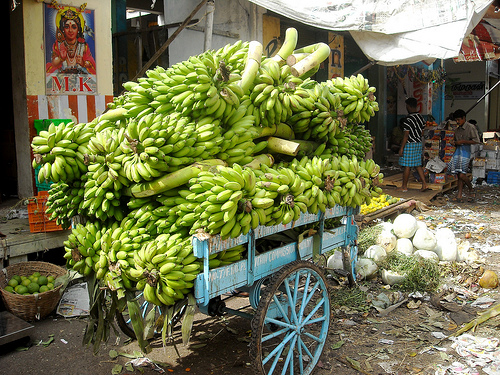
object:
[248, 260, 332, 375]
wheel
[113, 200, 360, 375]
cart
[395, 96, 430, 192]
person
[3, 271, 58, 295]
limes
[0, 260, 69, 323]
basket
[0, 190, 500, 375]
ground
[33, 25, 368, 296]
fruit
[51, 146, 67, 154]
banana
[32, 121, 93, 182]
bushel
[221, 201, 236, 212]
banana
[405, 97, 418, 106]
cap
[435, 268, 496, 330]
debris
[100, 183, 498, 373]
street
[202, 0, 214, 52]
pole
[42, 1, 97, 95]
poster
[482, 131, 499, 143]
box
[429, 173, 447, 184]
crate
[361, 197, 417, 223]
wood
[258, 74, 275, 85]
banana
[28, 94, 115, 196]
wall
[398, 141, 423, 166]
skirt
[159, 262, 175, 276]
banana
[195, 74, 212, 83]
banana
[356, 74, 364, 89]
banana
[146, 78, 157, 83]
banana